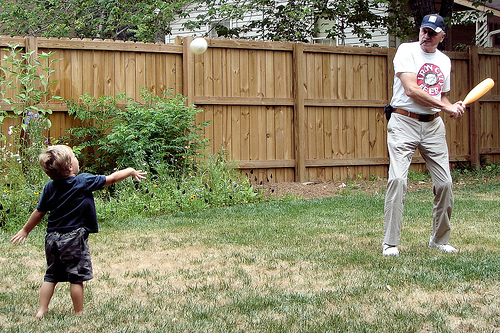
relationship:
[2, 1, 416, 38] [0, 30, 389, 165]
trees behind fence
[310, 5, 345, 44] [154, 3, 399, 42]
window on house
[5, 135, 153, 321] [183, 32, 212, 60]
child throwing ball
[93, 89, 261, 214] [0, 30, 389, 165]
bushes in front of fence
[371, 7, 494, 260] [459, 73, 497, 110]
man holding bat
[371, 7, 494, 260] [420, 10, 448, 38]
man wearing hat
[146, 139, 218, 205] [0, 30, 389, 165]
flowers next to fence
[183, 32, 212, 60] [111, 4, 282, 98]
ball in air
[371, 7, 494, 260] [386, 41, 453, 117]
man wearing white shirt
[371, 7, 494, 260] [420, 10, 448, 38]
man has cap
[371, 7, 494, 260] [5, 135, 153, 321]
man playing with boy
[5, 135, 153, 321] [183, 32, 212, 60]
boy throwing ball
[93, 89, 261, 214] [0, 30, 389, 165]
bushes against fence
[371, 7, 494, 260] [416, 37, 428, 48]
man has cigar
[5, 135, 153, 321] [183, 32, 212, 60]
boy threw ball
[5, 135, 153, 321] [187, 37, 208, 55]
boy playing ball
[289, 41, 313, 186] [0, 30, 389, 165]
post on fence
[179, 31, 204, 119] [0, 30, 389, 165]
post on fence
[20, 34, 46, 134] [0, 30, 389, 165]
post on fence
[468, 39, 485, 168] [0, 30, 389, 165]
post on fence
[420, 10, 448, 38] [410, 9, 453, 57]
hat on head